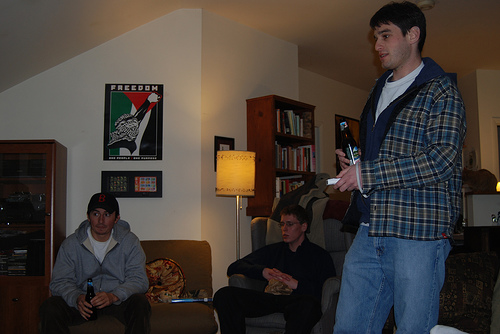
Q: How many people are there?
A: Three.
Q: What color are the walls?
A: White.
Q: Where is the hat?
A: On the guy's head.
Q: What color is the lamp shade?
A: Tan.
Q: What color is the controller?
A: White.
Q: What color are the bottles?
A: Brown.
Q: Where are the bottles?
A: In the guy's hands.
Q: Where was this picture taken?
A: In the living room of a home.